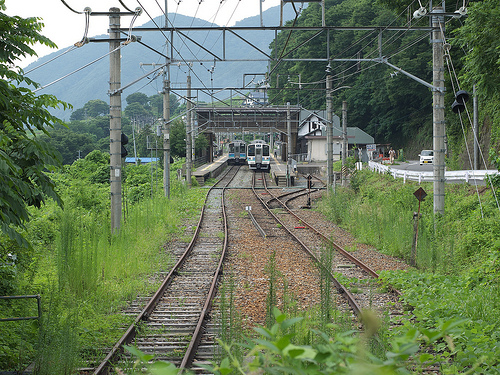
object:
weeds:
[218, 265, 228, 340]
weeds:
[324, 236, 333, 321]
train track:
[249, 168, 468, 375]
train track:
[90, 163, 241, 374]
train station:
[186, 102, 376, 189]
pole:
[109, 7, 124, 236]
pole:
[162, 80, 174, 200]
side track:
[267, 171, 322, 209]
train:
[246, 140, 272, 169]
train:
[225, 139, 249, 166]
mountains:
[0, 0, 312, 127]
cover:
[189, 106, 300, 133]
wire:
[159, 1, 183, 64]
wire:
[172, 1, 202, 62]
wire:
[192, 1, 224, 60]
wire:
[200, 1, 241, 61]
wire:
[294, 31, 434, 85]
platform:
[269, 151, 294, 178]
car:
[418, 149, 436, 166]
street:
[392, 151, 500, 185]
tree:
[1, 0, 74, 295]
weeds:
[325, 165, 499, 373]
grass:
[80, 192, 173, 280]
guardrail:
[353, 159, 499, 187]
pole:
[429, 7, 449, 218]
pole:
[324, 74, 337, 188]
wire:
[20, 38, 134, 96]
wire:
[8, 39, 82, 84]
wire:
[438, 25, 487, 226]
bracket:
[109, 89, 125, 96]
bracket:
[109, 105, 123, 110]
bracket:
[111, 126, 122, 133]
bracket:
[110, 151, 124, 156]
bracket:
[110, 179, 121, 184]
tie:
[121, 311, 229, 319]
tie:
[96, 345, 218, 353]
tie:
[137, 295, 229, 299]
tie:
[123, 309, 228, 314]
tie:
[93, 345, 224, 350]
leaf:
[67, 103, 74, 109]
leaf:
[25, 76, 32, 86]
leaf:
[21, 51, 27, 58]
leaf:
[32, 187, 40, 198]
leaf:
[21, 207, 31, 223]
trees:
[267, 1, 434, 146]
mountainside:
[267, 0, 433, 161]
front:
[247, 145, 270, 165]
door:
[255, 148, 261, 165]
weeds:
[350, 276, 359, 282]